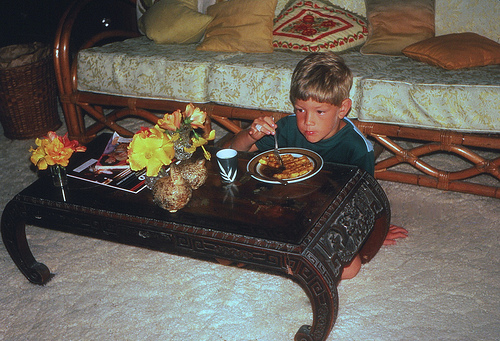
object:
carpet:
[414, 217, 478, 303]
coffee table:
[2, 130, 387, 338]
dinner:
[247, 146, 324, 185]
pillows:
[401, 32, 498, 67]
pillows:
[358, 0, 435, 58]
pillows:
[273, 2, 368, 55]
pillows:
[192, 0, 278, 53]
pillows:
[136, 4, 213, 42]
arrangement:
[28, 131, 87, 173]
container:
[50, 166, 70, 188]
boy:
[220, 50, 409, 279]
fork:
[272, 119, 281, 165]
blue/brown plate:
[245, 144, 325, 185]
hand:
[380, 222, 407, 246]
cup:
[214, 147, 240, 184]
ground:
[0, 95, 498, 339]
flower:
[178, 100, 207, 129]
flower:
[157, 109, 187, 132]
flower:
[123, 131, 179, 176]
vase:
[171, 131, 197, 161]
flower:
[26, 132, 83, 170]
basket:
[2, 44, 62, 139]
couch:
[61, 0, 498, 199]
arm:
[52, 2, 137, 144]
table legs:
[287, 274, 341, 341]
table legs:
[5, 208, 52, 289]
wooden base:
[55, 99, 496, 199]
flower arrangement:
[125, 130, 196, 212]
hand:
[248, 114, 276, 140]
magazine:
[94, 131, 173, 170]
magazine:
[68, 159, 154, 193]